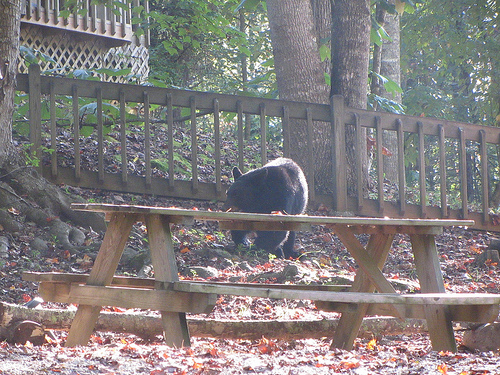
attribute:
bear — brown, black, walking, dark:
[226, 156, 312, 263]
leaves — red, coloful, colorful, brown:
[4, 191, 498, 375]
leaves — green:
[17, 3, 496, 171]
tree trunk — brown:
[264, 1, 403, 193]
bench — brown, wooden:
[24, 199, 500, 350]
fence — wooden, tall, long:
[0, 72, 500, 234]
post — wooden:
[142, 216, 178, 342]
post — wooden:
[65, 209, 135, 351]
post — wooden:
[399, 233, 455, 359]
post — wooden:
[330, 231, 394, 357]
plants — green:
[5, 89, 276, 186]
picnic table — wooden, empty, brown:
[19, 196, 500, 352]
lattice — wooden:
[1, 29, 148, 84]